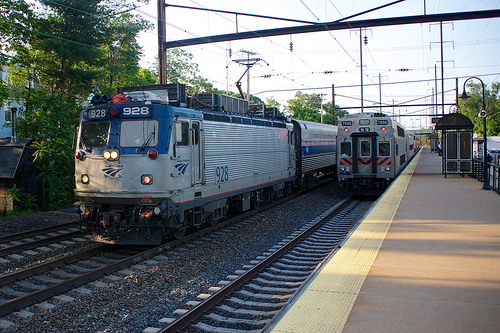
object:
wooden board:
[49, 269, 80, 279]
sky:
[0, 0, 499, 138]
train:
[335, 112, 423, 197]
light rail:
[72, 88, 336, 246]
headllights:
[79, 174, 152, 185]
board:
[1, 262, 114, 328]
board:
[228, 261, 308, 292]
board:
[177, 294, 284, 322]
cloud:
[187, 1, 345, 67]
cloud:
[316, 41, 412, 83]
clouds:
[2, 1, 499, 128]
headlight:
[143, 176, 151, 184]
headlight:
[81, 175, 88, 182]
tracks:
[4, 179, 379, 331]